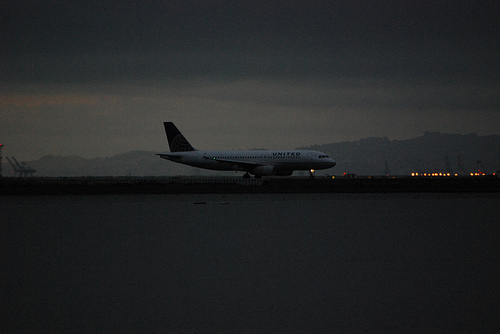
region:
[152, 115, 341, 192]
airplane on tarmac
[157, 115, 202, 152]
tail on top of airplane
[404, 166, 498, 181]
line of yellow lights lining tarmac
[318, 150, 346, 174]
nose of white airplane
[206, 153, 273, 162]
line of windows on side of airplane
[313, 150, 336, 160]
windshield on front of airplane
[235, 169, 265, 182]
wheels on bottom of airplane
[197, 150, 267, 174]
wing on side of airplane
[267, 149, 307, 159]
name on side of airplane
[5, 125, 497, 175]
rock structure bordering tarmac in background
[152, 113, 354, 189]
An airplane on a runway strip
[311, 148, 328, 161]
part of a window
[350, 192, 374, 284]
part of a runway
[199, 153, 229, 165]
part of a plane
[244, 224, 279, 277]
part of a runway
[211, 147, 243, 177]
edge of a wing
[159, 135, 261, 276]
part of a plane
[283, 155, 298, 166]
edge of a plane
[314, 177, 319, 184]
part of a wheel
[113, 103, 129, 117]
this is the sky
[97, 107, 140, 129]
the sky is blue in color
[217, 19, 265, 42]
the sky has clouds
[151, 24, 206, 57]
the clouds are black in color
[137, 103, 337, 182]
this is an airplane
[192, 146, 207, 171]
the plane is white in color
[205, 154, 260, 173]
this is a wing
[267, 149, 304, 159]
these are some writings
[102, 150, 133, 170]
this is a hill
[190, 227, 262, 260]
this is the runway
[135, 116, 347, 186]
a jet on a runway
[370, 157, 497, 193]
a row of lights in the distance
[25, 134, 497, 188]
a distant mountain range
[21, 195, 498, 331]
a flat stretch of concrete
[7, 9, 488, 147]
a dark cloudy sky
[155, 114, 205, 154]
a large jet's tail fin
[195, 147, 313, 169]
a row of windows on a plane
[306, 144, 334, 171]
a large jet's windshield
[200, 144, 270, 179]
a large jet's right wing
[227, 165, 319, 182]
a large jet's landing gear